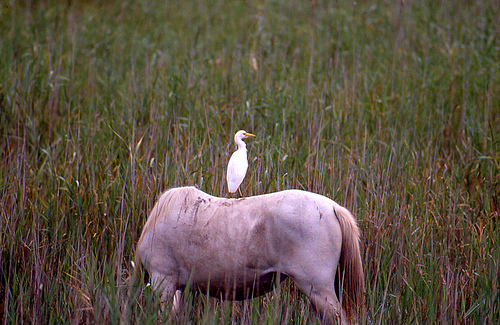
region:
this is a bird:
[228, 129, 250, 195]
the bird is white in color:
[228, 157, 240, 172]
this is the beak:
[243, 132, 257, 137]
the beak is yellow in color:
[244, 132, 259, 138]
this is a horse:
[166, 200, 333, 290]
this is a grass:
[71, 23, 242, 86]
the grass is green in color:
[263, 24, 303, 65]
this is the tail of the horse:
[339, 204, 364, 301]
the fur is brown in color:
[342, 250, 355, 275]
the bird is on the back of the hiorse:
[219, 126, 253, 199]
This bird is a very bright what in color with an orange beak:
[224, 116, 262, 214]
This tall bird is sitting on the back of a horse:
[225, 124, 257, 197]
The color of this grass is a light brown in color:
[212, 32, 305, 121]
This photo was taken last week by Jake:
[121, 63, 376, 307]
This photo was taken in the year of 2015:
[92, 22, 426, 279]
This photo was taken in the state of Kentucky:
[124, 29, 377, 298]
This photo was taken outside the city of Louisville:
[123, 21, 370, 313]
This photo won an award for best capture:
[106, 14, 343, 306]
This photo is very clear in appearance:
[135, 50, 382, 293]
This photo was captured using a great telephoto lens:
[88, 12, 390, 319]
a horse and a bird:
[125, 116, 385, 323]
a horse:
[125, 193, 388, 324]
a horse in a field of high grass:
[116, 183, 398, 324]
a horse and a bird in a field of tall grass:
[122, 107, 382, 319]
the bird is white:
[219, 124, 262, 202]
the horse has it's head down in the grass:
[96, 181, 406, 323]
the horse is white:
[110, 184, 418, 324]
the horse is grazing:
[106, 188, 424, 322]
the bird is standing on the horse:
[101, 117, 401, 324]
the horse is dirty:
[114, 193, 396, 320]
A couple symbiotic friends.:
[106, 105, 398, 313]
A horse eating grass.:
[104, 166, 387, 323]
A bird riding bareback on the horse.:
[209, 119, 270, 207]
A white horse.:
[108, 169, 390, 321]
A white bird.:
[214, 110, 269, 193]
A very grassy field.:
[1, 27, 498, 315]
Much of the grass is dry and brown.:
[20, 0, 478, 322]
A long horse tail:
[329, 201, 385, 324]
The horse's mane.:
[113, 182, 210, 280]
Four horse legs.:
[127, 258, 374, 324]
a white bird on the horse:
[219, 127, 260, 199]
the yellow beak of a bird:
[241, 130, 258, 140]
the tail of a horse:
[331, 197, 374, 322]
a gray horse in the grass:
[125, 183, 378, 323]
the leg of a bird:
[233, 183, 246, 199]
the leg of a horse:
[289, 270, 362, 323]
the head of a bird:
[234, 127, 259, 140]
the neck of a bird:
[229, 134, 248, 149]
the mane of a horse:
[125, 180, 197, 280]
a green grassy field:
[0, 0, 499, 323]